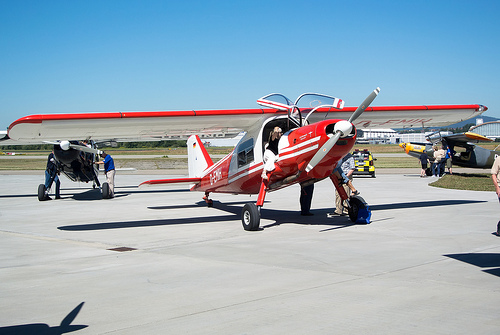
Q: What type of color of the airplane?
A: Red and white.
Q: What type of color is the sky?
A: Blue.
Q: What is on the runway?
A: Planes.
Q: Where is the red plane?
A: In the middle.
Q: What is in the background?
A: Buildings.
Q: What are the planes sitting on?
A: Cement.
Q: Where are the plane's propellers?
A: In front of the plane.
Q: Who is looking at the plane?
A: Adults.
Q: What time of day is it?
A: Afternoon.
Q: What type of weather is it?
A: Sunny.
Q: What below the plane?
A: Shadow.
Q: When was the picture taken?
A: During the day.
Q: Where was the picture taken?
A: Port.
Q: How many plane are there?
A: 3.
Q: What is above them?
A: The sky.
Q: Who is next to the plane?
A: A man.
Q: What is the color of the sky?
A: Blue.